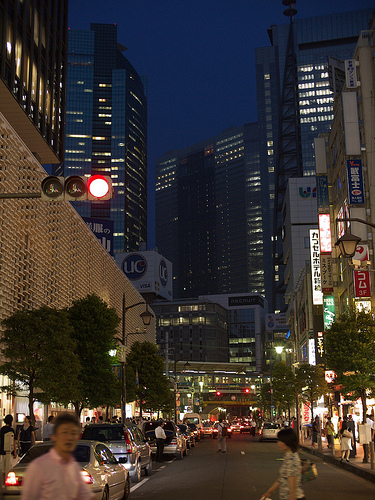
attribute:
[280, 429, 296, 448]
hair — black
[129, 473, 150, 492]
line — white, painted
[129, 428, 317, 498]
street — black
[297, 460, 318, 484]
shoulder bag — green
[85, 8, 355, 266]
sky — dark blue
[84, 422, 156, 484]
suv — gray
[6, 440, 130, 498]
car — small, silver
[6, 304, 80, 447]
tree — green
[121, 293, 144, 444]
pole — black, metal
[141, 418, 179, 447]
trunk — open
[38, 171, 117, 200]
traffic signal — red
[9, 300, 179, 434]
trees — small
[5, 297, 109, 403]
leaves — green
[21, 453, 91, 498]
shirt — pink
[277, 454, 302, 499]
shirt — dress